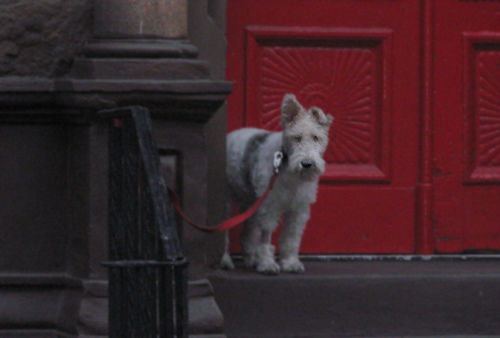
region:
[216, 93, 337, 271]
Brown and white dog.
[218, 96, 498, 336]
The dog is standing on a porch stoop.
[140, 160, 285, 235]
A red dog leash.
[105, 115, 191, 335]
Leash attached to a black handrail.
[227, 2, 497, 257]
Two red doors.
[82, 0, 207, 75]
Portion of a concrete post.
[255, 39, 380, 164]
Design carved into the door.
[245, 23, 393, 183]
Carved design with a square frame.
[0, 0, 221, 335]
A concrete building.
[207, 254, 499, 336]
A concrete door stoop.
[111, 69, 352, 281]
a dog with red leash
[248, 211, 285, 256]
a shaved part of leg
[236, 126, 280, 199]
a black strip on dog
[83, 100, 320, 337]
a dog chained to a rail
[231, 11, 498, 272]
a red door behind dog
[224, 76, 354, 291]
a white dog on a step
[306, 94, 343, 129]
one ear folded over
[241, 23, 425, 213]
a design on the door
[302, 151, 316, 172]
black nose of dog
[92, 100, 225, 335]
black railing to steps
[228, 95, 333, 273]
brown and white dog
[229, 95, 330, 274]
dog standing by door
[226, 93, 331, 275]
dog leashed to railing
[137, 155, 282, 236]
red leash on dog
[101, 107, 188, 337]
black iron railing on building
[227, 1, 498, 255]
red doors on building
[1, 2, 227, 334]
grey stone building with railing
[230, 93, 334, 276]
dog standing on stone step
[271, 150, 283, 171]
silver clasp on leash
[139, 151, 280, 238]
red leash with silver clasp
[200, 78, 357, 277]
A dog tied to the railing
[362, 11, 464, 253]
The doors are painted red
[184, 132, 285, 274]
The dogs leash is red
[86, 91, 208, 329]
The railing is wrought iron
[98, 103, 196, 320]
The railing is painted black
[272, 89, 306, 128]
One of the dogs ears is up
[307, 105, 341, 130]
This ear on the dog is down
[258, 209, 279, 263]
The dog had to have his leg shaved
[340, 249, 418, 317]
The steps are concrete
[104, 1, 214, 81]
The pillar is marble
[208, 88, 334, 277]
A medium sized white dog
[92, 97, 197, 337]
A black iron step railing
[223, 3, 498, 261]
Dog in front of an ornate red door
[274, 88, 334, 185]
Face of dog with one ear folded down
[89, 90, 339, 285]
Dog tied to a stair railing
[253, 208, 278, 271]
Leg of a dog with one strip shaved bare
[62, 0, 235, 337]
Ornate stone column on a building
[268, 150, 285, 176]
Metal clip on a dog leash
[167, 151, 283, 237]
A bright red dog leash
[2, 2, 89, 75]
Rough texture on a building wall